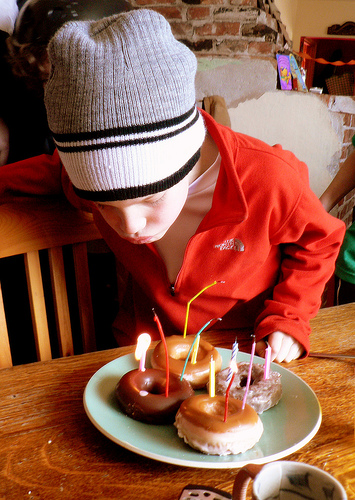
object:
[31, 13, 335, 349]
child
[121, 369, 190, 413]
doughnut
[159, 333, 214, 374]
doughnut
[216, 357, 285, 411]
doughnut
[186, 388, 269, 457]
doughnut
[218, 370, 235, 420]
candle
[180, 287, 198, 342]
candle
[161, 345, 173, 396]
candle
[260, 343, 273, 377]
candle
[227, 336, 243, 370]
candle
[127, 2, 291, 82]
brick wall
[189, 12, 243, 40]
brick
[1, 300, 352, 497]
table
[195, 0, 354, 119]
wall